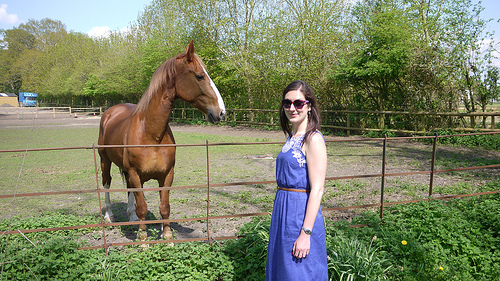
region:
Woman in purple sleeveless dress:
[266, 79, 328, 279]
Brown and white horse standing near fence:
[98, 38, 225, 250]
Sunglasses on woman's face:
[281, 95, 308, 108]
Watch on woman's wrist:
[300, 226, 310, 233]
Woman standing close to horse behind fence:
[96, 38, 328, 279]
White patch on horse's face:
[198, 61, 227, 125]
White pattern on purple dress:
[276, 135, 303, 165]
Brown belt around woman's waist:
[274, 183, 309, 193]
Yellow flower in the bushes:
[400, 237, 406, 245]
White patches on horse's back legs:
[101, 181, 138, 214]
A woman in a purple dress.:
[259, 80, 339, 279]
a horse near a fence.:
[75, 33, 241, 255]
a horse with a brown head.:
[170, 25, 241, 125]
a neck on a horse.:
[130, 72, 185, 150]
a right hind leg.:
[83, 141, 120, 235]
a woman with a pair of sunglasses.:
[281, 90, 312, 115]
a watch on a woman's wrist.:
[300, 226, 319, 237]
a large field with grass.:
[4, 108, 496, 246]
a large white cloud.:
[83, 20, 139, 42]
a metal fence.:
[0, 126, 497, 269]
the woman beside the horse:
[260, 73, 344, 260]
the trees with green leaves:
[167, 2, 444, 72]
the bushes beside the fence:
[28, 251, 292, 273]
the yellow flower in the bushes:
[387, 238, 417, 258]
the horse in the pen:
[74, 42, 239, 146]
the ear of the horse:
[177, 31, 196, 58]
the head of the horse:
[165, 33, 237, 123]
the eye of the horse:
[190, 68, 210, 86]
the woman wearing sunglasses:
[255, 65, 327, 148]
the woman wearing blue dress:
[249, 77, 337, 272]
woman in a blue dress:
[264, 78, 330, 279]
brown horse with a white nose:
[170, 38, 229, 130]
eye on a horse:
[191, 66, 205, 85]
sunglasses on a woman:
[281, 93, 311, 113]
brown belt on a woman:
[277, 181, 306, 194]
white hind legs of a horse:
[99, 184, 139, 228]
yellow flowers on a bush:
[360, 224, 422, 264]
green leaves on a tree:
[358, 34, 398, 99]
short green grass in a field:
[11, 130, 44, 142]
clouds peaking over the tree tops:
[81, 16, 108, 40]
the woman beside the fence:
[247, 73, 341, 278]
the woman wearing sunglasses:
[240, 71, 333, 278]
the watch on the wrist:
[297, 218, 317, 238]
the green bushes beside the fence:
[346, 195, 498, 278]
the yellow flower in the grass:
[398, 235, 415, 253]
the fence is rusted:
[0, 142, 478, 218]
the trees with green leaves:
[21, 35, 141, 97]